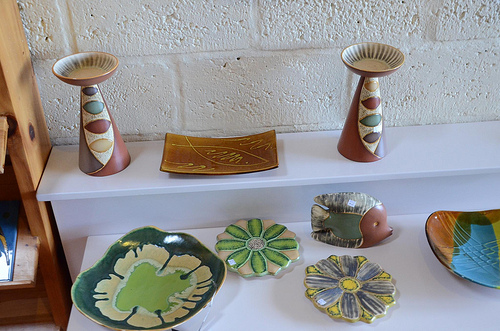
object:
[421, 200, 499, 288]
plate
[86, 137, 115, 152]
oval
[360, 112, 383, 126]
design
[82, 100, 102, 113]
design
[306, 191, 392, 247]
craft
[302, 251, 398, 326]
pottery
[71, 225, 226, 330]
bowl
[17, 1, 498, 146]
wall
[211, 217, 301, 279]
pottery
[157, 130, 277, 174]
craft dish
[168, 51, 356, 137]
brick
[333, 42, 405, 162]
holder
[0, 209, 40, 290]
book shelf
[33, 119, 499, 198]
shelf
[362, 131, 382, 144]
design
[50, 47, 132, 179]
holder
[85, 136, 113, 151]
design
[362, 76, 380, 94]
design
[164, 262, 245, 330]
shadow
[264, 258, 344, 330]
shadow